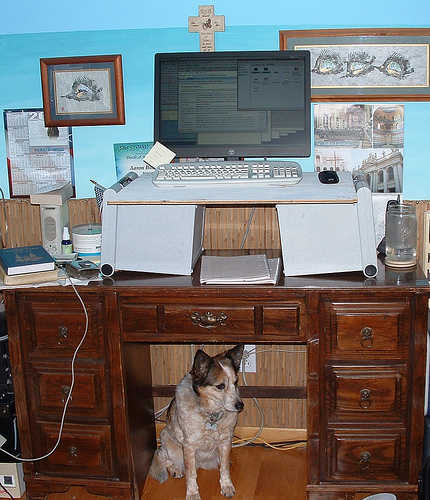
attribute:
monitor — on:
[151, 50, 313, 158]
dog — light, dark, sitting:
[145, 334, 250, 498]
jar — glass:
[380, 200, 423, 265]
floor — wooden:
[2, 443, 310, 498]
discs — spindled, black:
[72, 230, 102, 253]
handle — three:
[358, 326, 374, 352]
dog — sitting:
[159, 369, 251, 451]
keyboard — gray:
[161, 164, 293, 184]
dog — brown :
[141, 345, 260, 497]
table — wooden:
[6, 279, 423, 495]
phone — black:
[301, 159, 341, 188]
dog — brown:
[148, 343, 255, 497]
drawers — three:
[320, 297, 420, 488]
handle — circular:
[351, 451, 376, 471]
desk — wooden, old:
[4, 248, 429, 498]